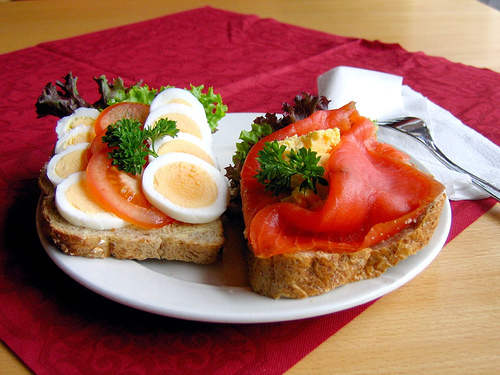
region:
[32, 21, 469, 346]
open sandwiches on white plate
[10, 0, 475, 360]
unfolded red napkin used as placemat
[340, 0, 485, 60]
light-colored wooden table under meal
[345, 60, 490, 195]
fork placed tines down on napkin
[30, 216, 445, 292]
slices of brown wheat bread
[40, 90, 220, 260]
two rows of sliced hard-boiled eggs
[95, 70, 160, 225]
tomato slices down middle of sandwich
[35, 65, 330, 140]
lettuce leaves poking out of sandwiches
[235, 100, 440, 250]
curled slices of smoked salmon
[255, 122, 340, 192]
chopped egg yolk and parsley in center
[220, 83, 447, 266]
A piece of salmon on bread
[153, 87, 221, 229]
Hard boiled eggs sliced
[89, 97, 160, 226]
Tomatoes sliced very thin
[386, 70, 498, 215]
A fork on a napkin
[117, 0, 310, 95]
A large red placemat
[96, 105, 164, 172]
Sprigs of parsley on tomatoes and eggs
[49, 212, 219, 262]
Wheat bread under eggs and tomatoes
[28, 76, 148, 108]
Kale is on plate too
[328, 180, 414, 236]
Red herring or salmon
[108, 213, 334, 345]
Sandwich is on a plate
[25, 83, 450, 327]
a two side sandwich on a plate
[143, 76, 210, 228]
a sliced boiled egg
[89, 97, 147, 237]
sliced tomatoes on a piece of bread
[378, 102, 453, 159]
a silver fork on a napking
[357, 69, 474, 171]
a white napkin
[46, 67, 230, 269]
boiled egg and tomato on a bread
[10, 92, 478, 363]
a white plate with food on it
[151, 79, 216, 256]
slices of boiled egg on bread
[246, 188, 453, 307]
a piece of wheat bread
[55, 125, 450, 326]
a round white plate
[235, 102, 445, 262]
this is lox, most people dont know what it is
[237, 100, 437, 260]
it's fancy lox, i cant tell you what kind [i dont eat pets], but this is pretty expensive stuff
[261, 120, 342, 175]
atop it, for some reason, seems like two teaspoons of scrambled eggs. i think it's caviar of some kind, in truth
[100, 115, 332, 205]
parsley on both sandwich sides is parsley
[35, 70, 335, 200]
then there's red leaf lettuce- the green lettuce is just the green part of the red, the red is the top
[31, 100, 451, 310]
a nice brown peasant bread, maybe two different types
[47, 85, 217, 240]
eight hard boiled egg slices, three tomato slices divide them four+four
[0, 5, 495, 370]
white plate, red cloth placemat, nice wooden table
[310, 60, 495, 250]
cloth napkin, white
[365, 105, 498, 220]
downturned silvertone, maybe silver, fork, tines turned away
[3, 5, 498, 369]
red placemat on table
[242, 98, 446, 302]
salmon on a slice of bread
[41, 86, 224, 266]
eight slice of hard boiled egg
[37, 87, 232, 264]
three tomato slices on bread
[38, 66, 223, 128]
green curly leaf lettuce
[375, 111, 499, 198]
stainless steel fork on table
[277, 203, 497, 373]
light grain of wood table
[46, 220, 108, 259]
seeds on bread crust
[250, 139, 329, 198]
small green sprig of parsley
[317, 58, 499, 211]
crumpled white paper napkin